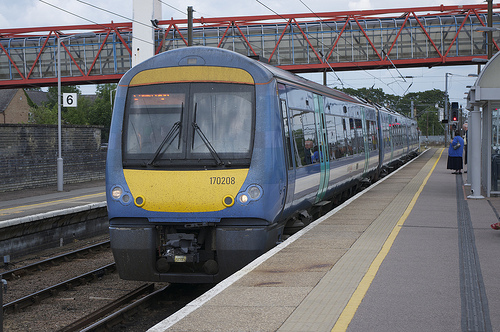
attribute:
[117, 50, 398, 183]
train — yellow, blue, fronted, at train station 6, number 170208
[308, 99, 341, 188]
double doors — green, closed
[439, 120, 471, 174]
woman — under stoplight, waiting for train, fat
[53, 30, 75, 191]
pole — gray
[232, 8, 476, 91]
bridge — red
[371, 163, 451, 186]
lines — yellow, white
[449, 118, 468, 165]
people — standing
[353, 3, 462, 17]
bars — red